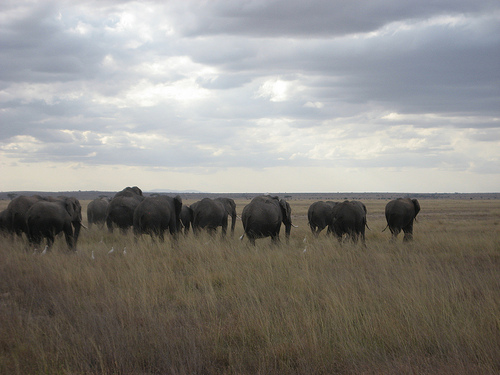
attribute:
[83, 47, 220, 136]
clouds — white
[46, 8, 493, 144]
sky — blue 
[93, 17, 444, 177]
sky — blue 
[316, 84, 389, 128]
clouds — white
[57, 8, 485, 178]
sky — blue 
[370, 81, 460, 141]
clouds — white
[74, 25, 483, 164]
sky — blue 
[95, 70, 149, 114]
clouds — white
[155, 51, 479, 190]
sky — blue 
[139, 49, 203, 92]
clouds — white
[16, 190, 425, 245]
cows — brown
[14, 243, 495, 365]
grass — tall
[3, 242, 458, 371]
grass — brown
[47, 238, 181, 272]
birds — White 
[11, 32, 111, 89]
sky — blue 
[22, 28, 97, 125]
clouds — white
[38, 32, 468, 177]
sky — blue 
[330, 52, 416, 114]
clouds — white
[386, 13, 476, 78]
clouds — white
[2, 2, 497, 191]
sky — blue 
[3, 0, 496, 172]
clouds — white, stormy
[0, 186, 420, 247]
elephants — drak gray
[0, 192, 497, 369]
grass — tall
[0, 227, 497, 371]
grass — tall, brown